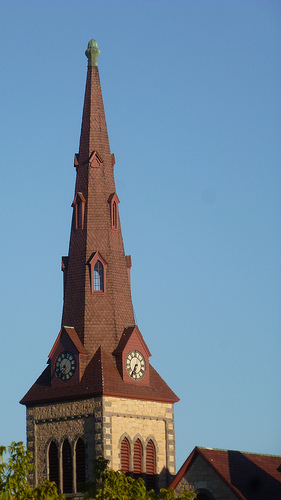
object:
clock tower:
[18, 34, 182, 498]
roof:
[17, 39, 183, 411]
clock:
[124, 350, 147, 383]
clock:
[55, 352, 78, 387]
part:
[72, 151, 79, 171]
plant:
[0, 440, 61, 500]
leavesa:
[92, 453, 196, 498]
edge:
[162, 446, 243, 500]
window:
[118, 434, 136, 486]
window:
[133, 434, 147, 486]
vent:
[145, 435, 158, 490]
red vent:
[74, 434, 91, 497]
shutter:
[61, 439, 73, 496]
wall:
[103, 397, 176, 498]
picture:
[2, 0, 275, 498]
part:
[227, 449, 279, 498]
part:
[190, 487, 211, 500]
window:
[190, 491, 213, 499]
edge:
[126, 247, 134, 274]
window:
[84, 253, 110, 296]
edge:
[101, 387, 180, 407]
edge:
[141, 355, 147, 382]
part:
[130, 364, 137, 378]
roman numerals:
[126, 348, 146, 383]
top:
[80, 30, 106, 72]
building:
[155, 444, 280, 499]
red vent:
[60, 435, 78, 499]